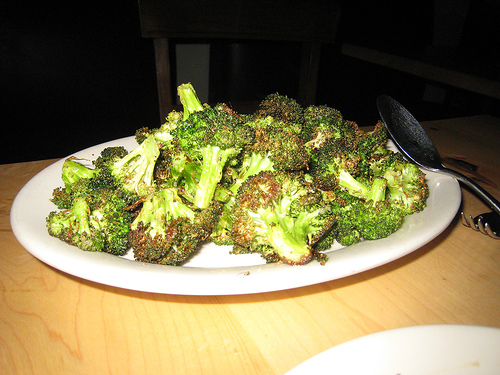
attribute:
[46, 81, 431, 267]
broccoli — cooked, green, piled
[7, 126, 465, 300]
plate — white, round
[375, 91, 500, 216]
utensils — silver, spoon, metal, gray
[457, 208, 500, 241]
utensils — silver, fork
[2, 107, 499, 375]
table — wooden, tan, brown, wood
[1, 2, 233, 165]
background — pitch black, black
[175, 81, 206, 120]
stem — green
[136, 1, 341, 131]
chair — dark brown, wooden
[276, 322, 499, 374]
plate — white